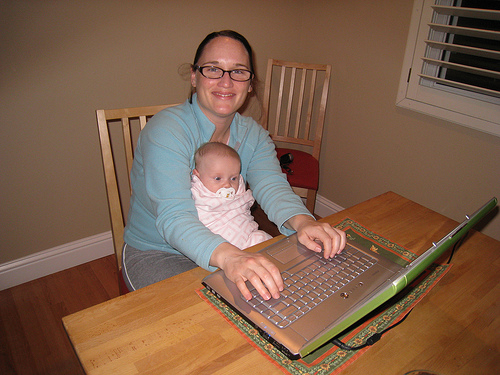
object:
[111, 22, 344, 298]
woman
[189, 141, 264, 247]
baby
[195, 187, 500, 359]
laptop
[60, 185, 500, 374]
table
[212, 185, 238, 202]
pacifier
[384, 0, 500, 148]
window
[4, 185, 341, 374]
flooring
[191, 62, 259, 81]
glasses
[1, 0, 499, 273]
wall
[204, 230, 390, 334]
keyboard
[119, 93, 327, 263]
shirt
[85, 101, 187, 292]
chair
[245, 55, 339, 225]
chair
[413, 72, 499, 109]
blind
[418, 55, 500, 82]
blind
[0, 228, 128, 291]
baseboard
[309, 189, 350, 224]
baseboard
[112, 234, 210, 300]
pants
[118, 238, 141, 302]
line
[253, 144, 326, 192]
seat